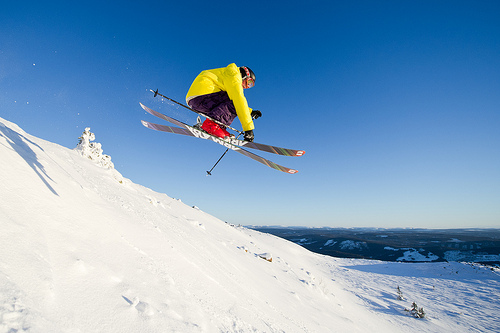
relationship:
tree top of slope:
[69, 126, 115, 171] [7, 114, 268, 321]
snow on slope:
[0, 114, 499, 333] [10, 130, 312, 330]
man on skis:
[184, 61, 262, 142] [130, 86, 310, 181]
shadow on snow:
[0, 114, 69, 211] [6, 116, 213, 331]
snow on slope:
[0, 114, 499, 333] [4, 124, 354, 331]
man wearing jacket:
[184, 61, 262, 142] [184, 41, 267, 141]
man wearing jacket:
[184, 61, 262, 142] [178, 47, 276, 138]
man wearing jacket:
[184, 61, 262, 142] [184, 45, 262, 134]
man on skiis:
[184, 61, 262, 142] [137, 96, 306, 176]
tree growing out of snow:
[388, 275, 420, 331] [333, 282, 348, 330]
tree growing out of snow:
[402, 299, 427, 320] [393, 272, 410, 306]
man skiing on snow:
[184, 61, 262, 142] [4, 118, 498, 317]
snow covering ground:
[4, 118, 498, 317] [15, 107, 494, 327]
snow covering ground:
[4, 118, 498, 317] [1, 120, 484, 319]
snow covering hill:
[0, 114, 499, 333] [338, 224, 486, 264]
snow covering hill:
[0, 114, 499, 333] [332, 232, 375, 259]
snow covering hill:
[0, 114, 499, 333] [437, 229, 463, 267]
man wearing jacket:
[184, 61, 262, 142] [188, 62, 257, 125]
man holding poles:
[184, 61, 262, 142] [210, 81, 253, 177]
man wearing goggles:
[184, 61, 262, 142] [237, 68, 265, 98]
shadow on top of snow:
[0, 120, 59, 197] [49, 160, 119, 233]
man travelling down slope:
[184, 61, 262, 142] [17, 142, 392, 332]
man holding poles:
[184, 61, 262, 142] [194, 99, 262, 174]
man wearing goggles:
[184, 61, 262, 142] [238, 70, 261, 95]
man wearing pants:
[184, 61, 262, 142] [191, 96, 242, 136]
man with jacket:
[184, 61, 262, 142] [188, 62, 257, 125]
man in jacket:
[184, 61, 262, 142] [178, 53, 268, 133]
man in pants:
[184, 61, 262, 142] [192, 90, 242, 135]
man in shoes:
[184, 61, 262, 142] [194, 114, 234, 142]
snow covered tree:
[0, 114, 499, 333] [71, 118, 121, 169]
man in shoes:
[184, 61, 262, 142] [198, 110, 231, 146]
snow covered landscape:
[0, 114, 499, 333] [2, 127, 482, 331]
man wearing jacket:
[184, 61, 262, 142] [180, 58, 263, 133]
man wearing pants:
[184, 61, 262, 142] [186, 91, 236, 128]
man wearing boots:
[184, 61, 262, 142] [196, 114, 233, 143]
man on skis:
[172, 47, 265, 146] [130, 101, 311, 174]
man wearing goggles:
[184, 61, 262, 142] [238, 65, 256, 90]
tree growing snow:
[79, 121, 115, 172] [24, 191, 254, 328]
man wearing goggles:
[184, 61, 262, 142] [244, 70, 256, 91]